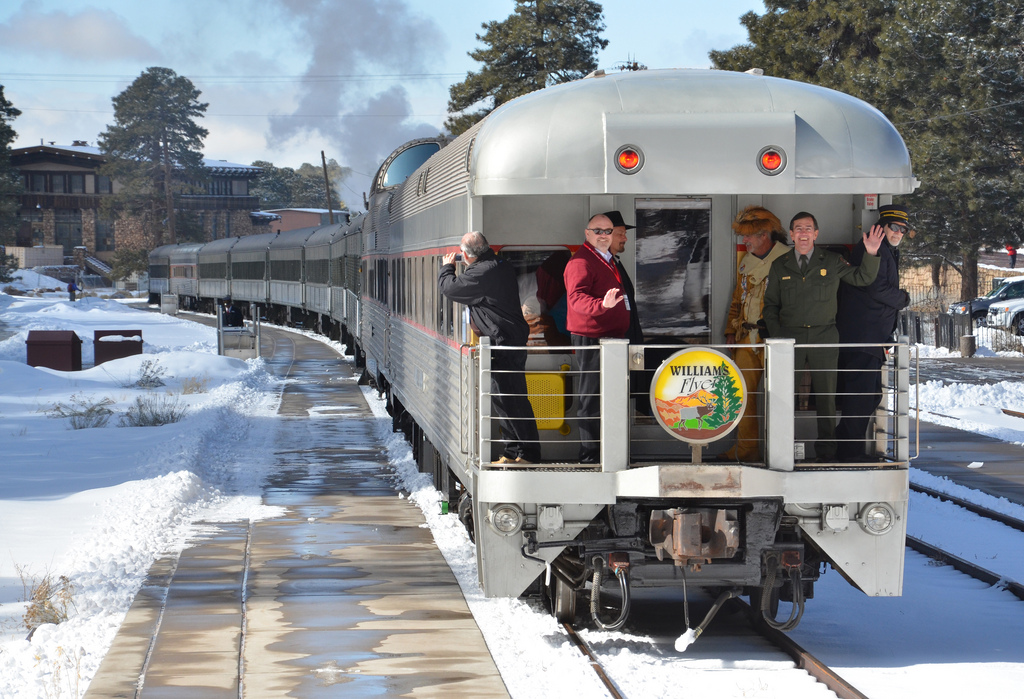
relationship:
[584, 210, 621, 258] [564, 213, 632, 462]
head of a man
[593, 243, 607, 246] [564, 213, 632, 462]
mouth of a man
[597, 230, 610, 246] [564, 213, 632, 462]
nose of a man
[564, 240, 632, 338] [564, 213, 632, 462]
jacket of a man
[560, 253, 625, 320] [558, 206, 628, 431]
arm of a man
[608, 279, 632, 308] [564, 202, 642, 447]
fingers of a man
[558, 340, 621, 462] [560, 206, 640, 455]
pants of a man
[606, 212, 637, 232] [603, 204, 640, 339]
hat of a man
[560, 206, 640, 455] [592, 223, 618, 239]
man wearing glasses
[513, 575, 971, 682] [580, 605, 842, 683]
snow on tracks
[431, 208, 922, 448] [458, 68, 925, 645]
people are shown on end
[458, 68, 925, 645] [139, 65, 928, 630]
end of train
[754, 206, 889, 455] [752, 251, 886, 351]
man with jacket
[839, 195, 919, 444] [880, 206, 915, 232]
man on far right wearing a hat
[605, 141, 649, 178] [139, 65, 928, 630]
light on a train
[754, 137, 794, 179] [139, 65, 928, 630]
light on a train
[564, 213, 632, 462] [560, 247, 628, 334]
man wearing a jacket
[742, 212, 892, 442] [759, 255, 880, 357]
man wearing a jacket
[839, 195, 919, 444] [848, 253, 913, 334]
man wearing a jacket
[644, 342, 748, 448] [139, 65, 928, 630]
sign on train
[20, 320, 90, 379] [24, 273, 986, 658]
trash bin in snow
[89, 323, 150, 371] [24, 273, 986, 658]
trash bin in snow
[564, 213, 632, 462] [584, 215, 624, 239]
man wearing sun glasses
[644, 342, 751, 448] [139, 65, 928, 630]
circle on front of train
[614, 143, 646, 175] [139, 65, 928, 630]
light on top of train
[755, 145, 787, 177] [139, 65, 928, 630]
light on top of train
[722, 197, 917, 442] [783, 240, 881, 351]
man in suit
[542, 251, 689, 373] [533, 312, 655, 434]
jacket with pants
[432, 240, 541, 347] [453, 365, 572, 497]
jacket with pants